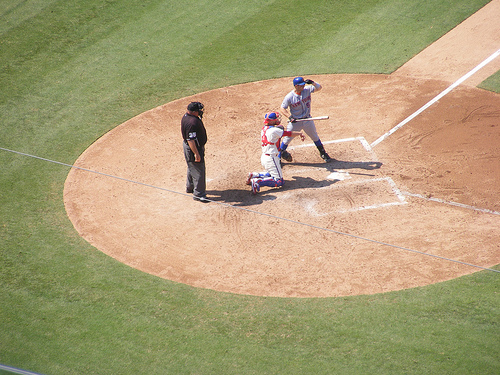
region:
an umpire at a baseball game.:
[164, 96, 222, 210]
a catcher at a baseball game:
[238, 102, 308, 203]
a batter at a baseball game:
[274, 66, 344, 166]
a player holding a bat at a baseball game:
[279, 109, 338, 130]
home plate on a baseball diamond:
[318, 160, 353, 188]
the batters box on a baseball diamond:
[255, 122, 401, 172]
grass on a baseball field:
[17, 42, 139, 106]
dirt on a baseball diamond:
[428, 127, 484, 178]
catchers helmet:
[255, 106, 290, 128]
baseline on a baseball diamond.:
[391, 57, 483, 128]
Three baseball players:
[167, 71, 347, 208]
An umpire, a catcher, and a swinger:
[175, 74, 337, 203]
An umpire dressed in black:
[172, 99, 232, 207]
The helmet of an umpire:
[182, 96, 208, 123]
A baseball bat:
[287, 112, 332, 124]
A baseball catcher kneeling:
[244, 110, 305, 195]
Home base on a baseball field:
[273, 130, 410, 220]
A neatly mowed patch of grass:
[22, 275, 153, 367]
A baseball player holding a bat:
[282, 73, 337, 168]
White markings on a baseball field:
[333, 119, 444, 215]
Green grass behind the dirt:
[42, 47, 147, 108]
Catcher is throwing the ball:
[236, 94, 322, 211]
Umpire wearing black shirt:
[159, 94, 214, 163]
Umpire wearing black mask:
[178, 100, 210, 125]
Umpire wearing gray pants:
[163, 136, 218, 213]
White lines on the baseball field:
[372, 88, 474, 158]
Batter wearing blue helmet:
[281, 71, 333, 105]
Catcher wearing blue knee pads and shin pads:
[238, 150, 302, 212]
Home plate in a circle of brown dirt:
[90, 79, 477, 269]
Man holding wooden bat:
[281, 85, 349, 150]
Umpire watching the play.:
[167, 85, 241, 217]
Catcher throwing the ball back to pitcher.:
[236, 106, 323, 248]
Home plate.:
[318, 107, 366, 217]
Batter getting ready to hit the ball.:
[261, 53, 373, 179]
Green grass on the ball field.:
[95, 63, 170, 131]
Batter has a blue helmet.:
[261, 13, 339, 174]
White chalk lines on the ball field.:
[342, 119, 390, 314]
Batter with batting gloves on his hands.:
[242, 66, 355, 196]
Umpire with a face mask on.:
[171, 97, 236, 248]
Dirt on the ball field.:
[223, 153, 281, 260]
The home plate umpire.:
[172, 97, 217, 197]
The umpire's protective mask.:
[184, 98, 225, 111]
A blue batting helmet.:
[290, 74, 304, 88]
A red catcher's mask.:
[271, 111, 281, 123]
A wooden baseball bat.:
[292, 114, 334, 124]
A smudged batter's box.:
[304, 177, 416, 217]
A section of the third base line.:
[434, 51, 479, 116]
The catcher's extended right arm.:
[277, 129, 311, 143]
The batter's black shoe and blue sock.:
[310, 140, 336, 160]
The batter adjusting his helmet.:
[278, 74, 340, 105]